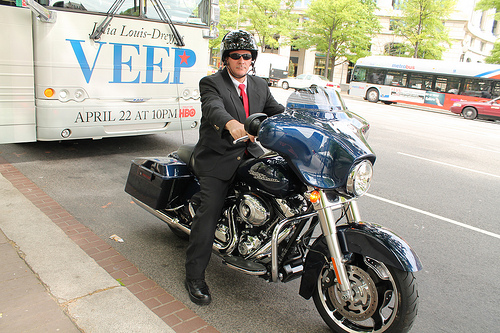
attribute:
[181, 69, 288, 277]
suit — black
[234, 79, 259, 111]
tie — red 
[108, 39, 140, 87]
letter — blue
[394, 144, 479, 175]
line — white 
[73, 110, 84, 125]
letter — black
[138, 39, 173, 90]
letter — blue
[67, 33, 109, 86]
letter — black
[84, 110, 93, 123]
letter — black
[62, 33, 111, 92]
letter — blue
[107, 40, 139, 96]
letter — blue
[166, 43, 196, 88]
letter — blue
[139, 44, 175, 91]
letter — blue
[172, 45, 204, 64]
star — blue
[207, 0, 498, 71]
trees — green 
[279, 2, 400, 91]
leaves — green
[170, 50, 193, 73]
star — red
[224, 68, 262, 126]
tie — red